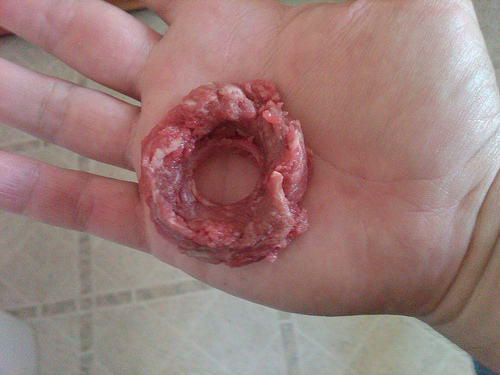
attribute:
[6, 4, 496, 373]
person — open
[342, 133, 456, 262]
flesh — light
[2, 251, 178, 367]
tile — white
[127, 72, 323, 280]
meat — circular, round, red, a roll, beef